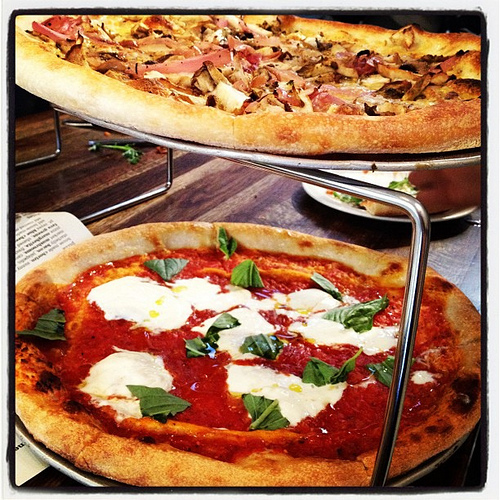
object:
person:
[408, 163, 481, 214]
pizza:
[13, 9, 481, 155]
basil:
[231, 258, 265, 288]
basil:
[125, 384, 192, 417]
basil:
[241, 393, 290, 430]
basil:
[16, 309, 68, 341]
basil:
[322, 293, 389, 332]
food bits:
[87, 142, 142, 165]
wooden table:
[57, 151, 257, 216]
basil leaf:
[230, 259, 265, 287]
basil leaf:
[217, 226, 237, 260]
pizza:
[14, 221, 479, 487]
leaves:
[302, 345, 364, 387]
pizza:
[326, 171, 418, 217]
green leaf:
[310, 272, 342, 301]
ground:
[441, 168, 468, 191]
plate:
[301, 169, 477, 224]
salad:
[388, 177, 418, 195]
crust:
[374, 202, 406, 216]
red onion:
[312, 91, 347, 112]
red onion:
[32, 21, 70, 42]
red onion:
[227, 35, 243, 49]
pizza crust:
[59, 238, 124, 267]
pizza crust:
[80, 445, 139, 470]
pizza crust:
[444, 392, 474, 424]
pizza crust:
[205, 123, 305, 145]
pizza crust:
[360, 115, 461, 147]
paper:
[8, 212, 95, 490]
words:
[28, 219, 49, 248]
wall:
[106, 124, 160, 145]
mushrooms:
[24, 15, 480, 117]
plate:
[14, 418, 471, 490]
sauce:
[55, 268, 456, 458]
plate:
[50, 102, 480, 171]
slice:
[326, 170, 414, 218]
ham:
[137, 49, 231, 76]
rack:
[11, 105, 485, 489]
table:
[9, 89, 488, 494]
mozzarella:
[76, 275, 434, 428]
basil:
[144, 257, 190, 280]